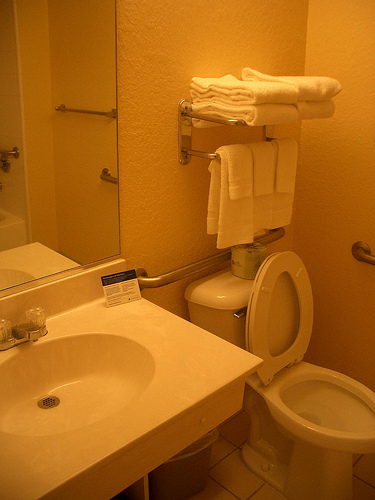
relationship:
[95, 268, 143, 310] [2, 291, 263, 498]
sign on counter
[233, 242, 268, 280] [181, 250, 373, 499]
tissue on toilet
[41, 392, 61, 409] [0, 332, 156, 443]
drain in sink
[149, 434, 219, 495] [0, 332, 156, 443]
can under sink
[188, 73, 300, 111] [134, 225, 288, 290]
towel over handle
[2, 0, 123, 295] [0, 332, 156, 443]
mirror over sink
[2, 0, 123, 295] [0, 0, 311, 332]
mirror on wall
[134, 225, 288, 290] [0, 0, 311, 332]
handle on wall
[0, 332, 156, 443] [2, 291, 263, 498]
sink in counter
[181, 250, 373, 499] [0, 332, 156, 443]
toilet by sink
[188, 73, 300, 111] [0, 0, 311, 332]
towel on wall